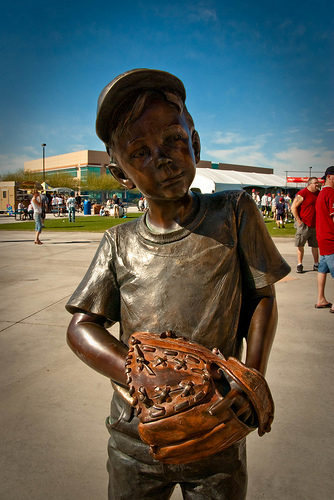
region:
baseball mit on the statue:
[123, 328, 277, 465]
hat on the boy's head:
[91, 62, 188, 144]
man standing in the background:
[318, 155, 332, 319]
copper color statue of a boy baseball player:
[64, 68, 280, 496]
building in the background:
[9, 145, 285, 221]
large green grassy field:
[2, 217, 298, 238]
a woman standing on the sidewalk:
[30, 186, 44, 243]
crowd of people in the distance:
[1, 168, 293, 228]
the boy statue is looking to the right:
[93, 61, 226, 222]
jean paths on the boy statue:
[99, 384, 248, 496]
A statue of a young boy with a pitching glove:
[55, 61, 293, 495]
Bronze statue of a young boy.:
[60, 66, 292, 498]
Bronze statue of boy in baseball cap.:
[62, 64, 299, 498]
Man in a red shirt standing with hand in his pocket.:
[288, 173, 324, 278]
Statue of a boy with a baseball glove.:
[61, 64, 290, 462]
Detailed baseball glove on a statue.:
[117, 322, 284, 468]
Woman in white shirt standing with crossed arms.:
[23, 181, 47, 252]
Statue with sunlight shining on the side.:
[45, 57, 291, 497]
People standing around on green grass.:
[248, 181, 301, 238]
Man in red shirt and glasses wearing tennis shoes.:
[288, 172, 323, 276]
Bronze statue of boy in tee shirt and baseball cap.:
[57, 61, 305, 489]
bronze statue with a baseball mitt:
[62, 78, 309, 496]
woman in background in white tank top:
[23, 186, 51, 246]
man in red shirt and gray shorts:
[284, 170, 327, 272]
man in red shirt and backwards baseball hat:
[317, 164, 333, 255]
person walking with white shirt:
[64, 194, 78, 223]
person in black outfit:
[273, 195, 287, 231]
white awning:
[194, 162, 309, 195]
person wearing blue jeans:
[63, 194, 77, 225]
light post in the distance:
[39, 138, 50, 205]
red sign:
[280, 169, 325, 185]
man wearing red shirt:
[317, 204, 328, 226]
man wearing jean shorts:
[321, 258, 331, 263]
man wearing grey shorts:
[297, 231, 305, 237]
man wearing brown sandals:
[313, 297, 333, 315]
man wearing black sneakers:
[292, 257, 312, 276]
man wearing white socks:
[297, 261, 302, 266]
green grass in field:
[89, 217, 106, 227]